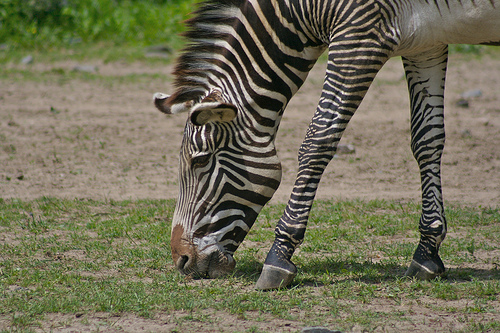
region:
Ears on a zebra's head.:
[149, 88, 239, 125]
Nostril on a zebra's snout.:
[176, 251, 193, 271]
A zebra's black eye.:
[191, 152, 213, 165]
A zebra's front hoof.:
[253, 258, 298, 288]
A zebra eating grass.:
[152, 0, 499, 293]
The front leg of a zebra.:
[255, 10, 398, 299]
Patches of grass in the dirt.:
[1, 194, 498, 330]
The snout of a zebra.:
[168, 173, 254, 275]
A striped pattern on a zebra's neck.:
[211, 8, 316, 87]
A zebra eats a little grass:
[154, 0, 499, 293]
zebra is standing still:
[152, 2, 499, 292]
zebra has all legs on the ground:
[148, 1, 498, 291]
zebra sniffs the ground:
[150, 0, 492, 292]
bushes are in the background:
[0, 0, 192, 52]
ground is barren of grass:
[0, 51, 496, 207]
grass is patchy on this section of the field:
[0, 196, 497, 326]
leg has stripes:
[400, 50, 455, 280]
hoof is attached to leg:
[251, 256, 296, 291]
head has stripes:
[145, 87, 286, 279]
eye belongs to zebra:
[185, 148, 212, 170]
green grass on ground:
[161, 277, 193, 315]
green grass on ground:
[113, 283, 143, 310]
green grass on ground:
[108, 252, 156, 274]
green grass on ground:
[126, 213, 154, 248]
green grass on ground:
[146, 204, 168, 234]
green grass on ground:
[100, 216, 122, 239]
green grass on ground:
[44, 249, 94, 294]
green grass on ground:
[321, 213, 350, 265]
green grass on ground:
[318, 256, 383, 316]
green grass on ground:
[451, 209, 483, 244]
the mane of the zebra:
[165, 0, 226, 105]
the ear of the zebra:
[185, 97, 235, 123]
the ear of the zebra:
[150, 87, 185, 112]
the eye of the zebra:
[187, 148, 210, 168]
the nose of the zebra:
[170, 223, 198, 274]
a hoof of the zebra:
[255, 261, 293, 291]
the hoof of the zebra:
[405, 251, 443, 281]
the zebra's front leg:
[255, 45, 395, 290]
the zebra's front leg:
[400, 45, 451, 280]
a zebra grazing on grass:
[151, 2, 498, 294]